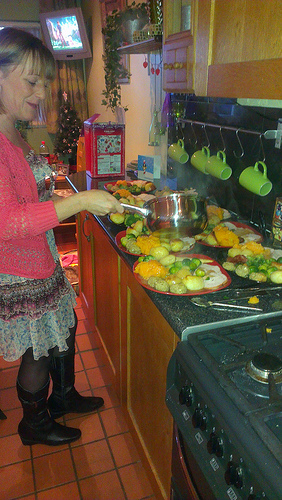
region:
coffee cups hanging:
[119, 104, 279, 222]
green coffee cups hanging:
[137, 89, 278, 238]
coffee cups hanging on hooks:
[155, 95, 281, 227]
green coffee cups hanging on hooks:
[164, 96, 280, 210]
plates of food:
[106, 172, 275, 321]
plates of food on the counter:
[122, 156, 280, 289]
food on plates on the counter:
[86, 156, 279, 330]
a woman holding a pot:
[10, 30, 260, 253]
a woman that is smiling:
[12, 20, 78, 142]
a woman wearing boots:
[8, 44, 129, 498]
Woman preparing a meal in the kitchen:
[0, 26, 125, 451]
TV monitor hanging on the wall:
[36, 4, 94, 64]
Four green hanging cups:
[165, 135, 274, 198]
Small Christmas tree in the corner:
[50, 86, 85, 171]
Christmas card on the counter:
[135, 152, 164, 183]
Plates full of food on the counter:
[101, 177, 281, 301]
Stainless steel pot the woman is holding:
[119, 191, 210, 240]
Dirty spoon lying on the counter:
[187, 292, 265, 316]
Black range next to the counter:
[163, 305, 281, 498]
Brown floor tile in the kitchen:
[2, 219, 161, 496]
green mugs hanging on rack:
[165, 131, 278, 220]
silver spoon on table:
[189, 294, 272, 327]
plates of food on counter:
[100, 176, 281, 311]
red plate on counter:
[127, 250, 232, 313]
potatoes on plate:
[150, 243, 178, 266]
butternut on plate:
[126, 246, 176, 279]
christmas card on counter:
[126, 139, 171, 197]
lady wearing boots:
[15, 373, 81, 449]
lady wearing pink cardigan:
[0, 112, 75, 282]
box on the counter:
[71, 103, 143, 190]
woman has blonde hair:
[4, 37, 65, 84]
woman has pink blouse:
[1, 130, 38, 252]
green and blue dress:
[6, 149, 82, 352]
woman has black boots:
[0, 343, 85, 470]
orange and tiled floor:
[10, 438, 144, 495]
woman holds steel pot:
[147, 146, 212, 255]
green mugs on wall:
[153, 124, 259, 209]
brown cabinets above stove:
[139, 11, 277, 128]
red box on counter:
[80, 115, 123, 178]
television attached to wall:
[34, 12, 102, 64]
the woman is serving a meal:
[0, 27, 271, 316]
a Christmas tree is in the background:
[55, 89, 88, 163]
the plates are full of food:
[96, 174, 274, 314]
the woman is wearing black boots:
[9, 340, 109, 451]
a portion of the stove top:
[198, 322, 280, 444]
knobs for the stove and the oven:
[183, 380, 253, 497]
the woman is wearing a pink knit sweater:
[1, 131, 64, 290]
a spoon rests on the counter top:
[191, 294, 275, 314]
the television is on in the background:
[32, 11, 93, 66]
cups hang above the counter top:
[169, 129, 266, 198]